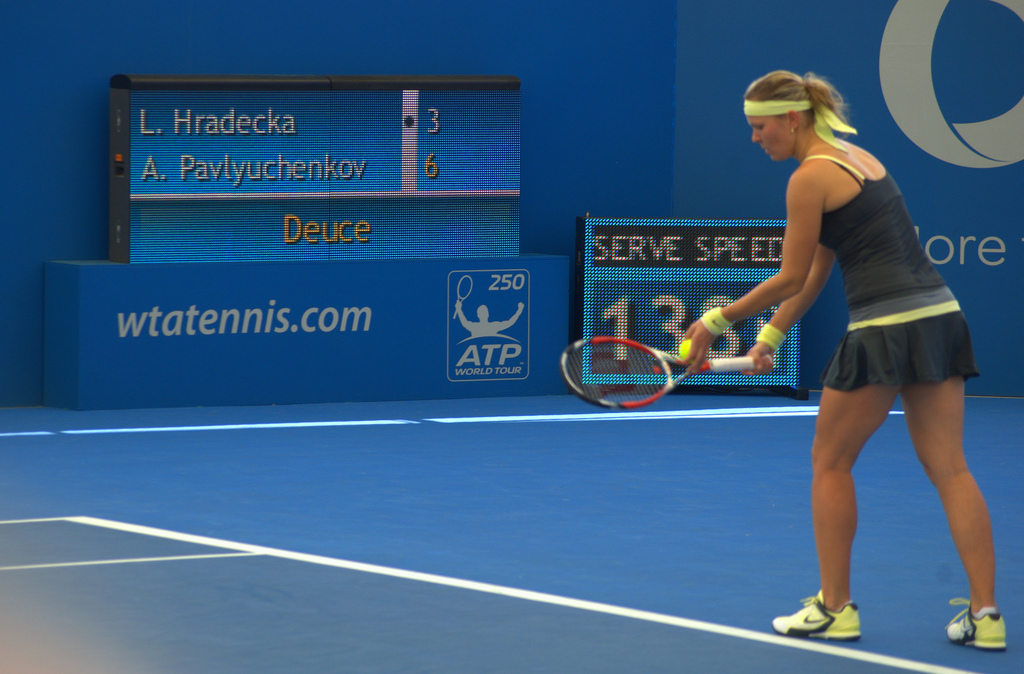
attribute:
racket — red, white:
[555, 323, 778, 414]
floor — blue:
[8, 385, 1020, 664]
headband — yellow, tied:
[740, 87, 818, 120]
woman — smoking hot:
[678, 61, 1013, 664]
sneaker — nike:
[762, 575, 875, 647]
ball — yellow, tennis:
[673, 333, 712, 372]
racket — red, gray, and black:
[555, 329, 703, 420]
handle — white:
[700, 348, 759, 374]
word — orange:
[277, 212, 386, 247]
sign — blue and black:
[575, 208, 805, 407]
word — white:
[592, 229, 787, 268]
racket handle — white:
[700, 346, 772, 368]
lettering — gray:
[110, 297, 381, 336]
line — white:
[63, 510, 971, 670]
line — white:
[0, 543, 273, 576]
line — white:
[0, 508, 93, 526]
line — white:
[2, 396, 906, 440]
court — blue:
[0, 392, 1024, 669]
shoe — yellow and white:
[938, 592, 1016, 655]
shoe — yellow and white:
[765, 582, 878, 643]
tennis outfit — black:
[806, 147, 990, 392]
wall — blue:
[0, 0, 1024, 400]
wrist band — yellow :
[704, 302, 737, 339]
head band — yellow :
[746, 99, 814, 115]